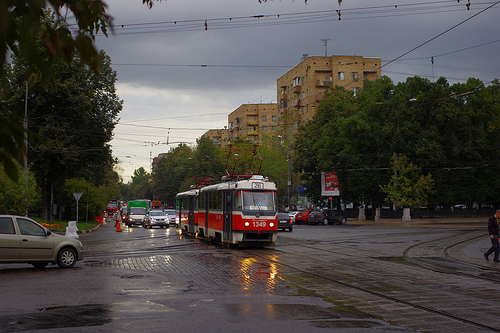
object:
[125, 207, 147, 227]
car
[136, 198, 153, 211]
vehicles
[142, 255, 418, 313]
rain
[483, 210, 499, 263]
man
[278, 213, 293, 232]
automobiles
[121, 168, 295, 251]
traffic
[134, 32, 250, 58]
clouds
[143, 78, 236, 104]
sky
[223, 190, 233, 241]
door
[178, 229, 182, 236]
light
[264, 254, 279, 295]
reflection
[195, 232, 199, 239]
light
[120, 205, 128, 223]
vehicle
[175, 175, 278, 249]
bus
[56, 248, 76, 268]
tire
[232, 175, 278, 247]
front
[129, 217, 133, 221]
headlights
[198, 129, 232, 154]
buildings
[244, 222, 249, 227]
headlights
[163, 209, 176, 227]
cars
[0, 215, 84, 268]
car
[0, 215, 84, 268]
side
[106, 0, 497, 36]
wires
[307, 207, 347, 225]
vehicle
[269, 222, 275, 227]
headlights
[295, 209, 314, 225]
vehicle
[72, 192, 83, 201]
sign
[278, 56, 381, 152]
building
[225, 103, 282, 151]
building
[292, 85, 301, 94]
balcony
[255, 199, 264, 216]
wiper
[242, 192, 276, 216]
window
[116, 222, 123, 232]
cone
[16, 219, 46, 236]
window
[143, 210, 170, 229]
car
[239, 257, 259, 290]
reflection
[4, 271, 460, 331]
pavement